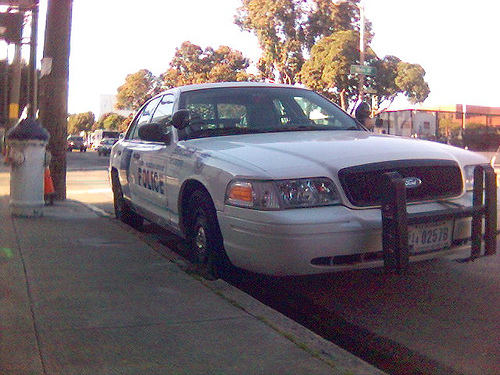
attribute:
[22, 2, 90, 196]
brown pole — brown 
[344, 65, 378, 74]
street sign — green , white 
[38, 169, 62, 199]
cone — small , orange 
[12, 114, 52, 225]
fire hydrant — white , blue 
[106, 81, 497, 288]
police car — white 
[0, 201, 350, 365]
cement sidewalk — cement 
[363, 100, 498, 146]
white building — white , large 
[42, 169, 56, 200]
pylon — orange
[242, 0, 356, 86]
trees — tall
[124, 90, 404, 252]
police car — white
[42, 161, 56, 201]
cone — orange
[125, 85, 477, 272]
police car — white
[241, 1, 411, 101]
tree — tall, leafy, green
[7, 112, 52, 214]
fire hydrant — blue , white 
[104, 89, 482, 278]
car — white